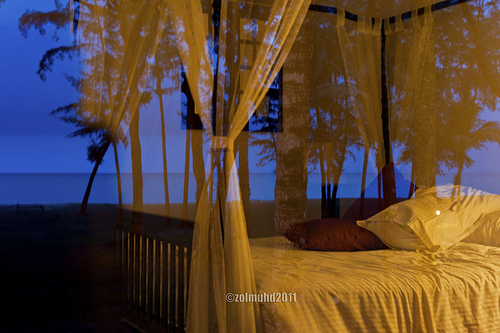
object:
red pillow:
[341, 165, 418, 229]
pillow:
[283, 219, 387, 250]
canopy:
[92, 0, 495, 29]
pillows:
[283, 160, 500, 252]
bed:
[118, 201, 498, 331]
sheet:
[120, 234, 500, 333]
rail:
[113, 209, 221, 249]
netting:
[67, 0, 482, 173]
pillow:
[356, 183, 500, 252]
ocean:
[0, 174, 497, 206]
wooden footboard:
[108, 208, 195, 329]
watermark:
[225, 293, 296, 303]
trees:
[18, 0, 496, 230]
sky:
[0, 0, 500, 204]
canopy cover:
[79, 2, 491, 332]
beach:
[3, 190, 499, 330]